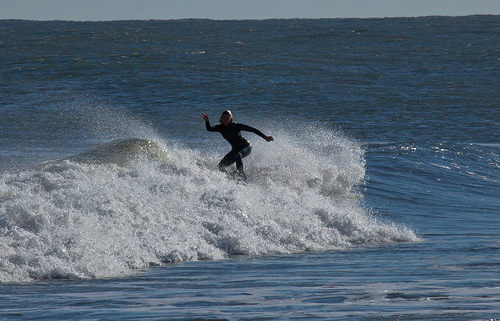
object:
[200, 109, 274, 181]
person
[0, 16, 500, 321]
water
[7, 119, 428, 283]
waves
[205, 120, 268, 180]
wetsuit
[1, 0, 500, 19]
sky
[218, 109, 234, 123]
hair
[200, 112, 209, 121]
hand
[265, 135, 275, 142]
hand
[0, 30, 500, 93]
calm waters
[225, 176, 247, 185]
surfboard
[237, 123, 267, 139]
arm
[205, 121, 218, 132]
arm